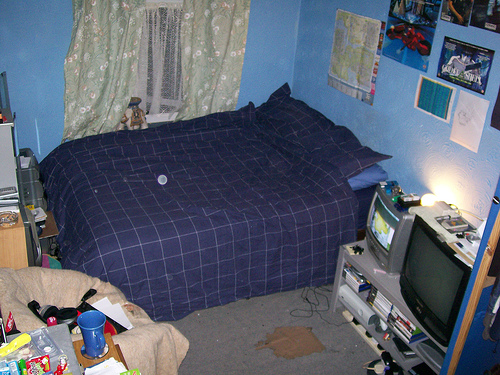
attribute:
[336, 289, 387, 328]
game system — xbox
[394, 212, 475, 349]
tv — black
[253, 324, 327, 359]
stain — large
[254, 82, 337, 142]
case — blue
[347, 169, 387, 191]
pillow — blue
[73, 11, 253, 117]
curtains — patterned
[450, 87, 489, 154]
paper — white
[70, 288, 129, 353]
mug — blue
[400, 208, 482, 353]
tv — black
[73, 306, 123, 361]
cup — blue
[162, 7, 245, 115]
curtains — green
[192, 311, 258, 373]
carpet — tan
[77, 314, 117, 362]
blue mug — light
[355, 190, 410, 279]
tv — small, gray